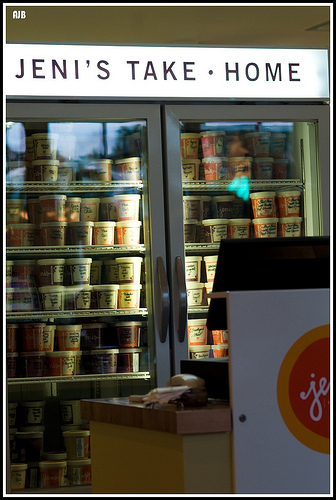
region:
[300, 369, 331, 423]
White writing on an orange background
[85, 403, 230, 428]
A brown counter top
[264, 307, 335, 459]
An orange circle surrounded by a yellow circle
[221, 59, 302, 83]
Black lettered word on white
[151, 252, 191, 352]
Handles on a refrigerated case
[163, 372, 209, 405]
Telephone on a counter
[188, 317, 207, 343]
Orange and white container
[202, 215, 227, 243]
Brown and white container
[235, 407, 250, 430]
Metal round circle on white background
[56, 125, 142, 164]
Reflections of the outside on glass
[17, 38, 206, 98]
Lighted sign on display.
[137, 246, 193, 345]
Metal handles on doors.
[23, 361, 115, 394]
Wire shelving in unit.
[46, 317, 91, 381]
Containers of ice cream.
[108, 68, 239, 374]
Refridgerated unit holding containers.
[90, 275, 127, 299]
White lid on container.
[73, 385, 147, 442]
Wood counter top on base.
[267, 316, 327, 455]
Red and orange logo on counter.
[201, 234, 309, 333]
Black monitor in store.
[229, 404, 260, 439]
Screw holding sign to counter.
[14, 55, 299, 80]
Black letters on white sign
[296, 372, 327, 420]
White letters on sign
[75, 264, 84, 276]
Black lettering on container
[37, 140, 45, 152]
Black lettering on container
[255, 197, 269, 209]
Black lettering on orange container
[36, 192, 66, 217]
Orange container behind glass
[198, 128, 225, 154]
Container behind glass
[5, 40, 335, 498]
Clear glass doors below white sign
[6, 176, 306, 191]
White rack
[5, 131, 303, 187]
White rack under containers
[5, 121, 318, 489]
A display of ice cream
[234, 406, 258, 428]
A small black screw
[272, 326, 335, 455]
A logo on the counter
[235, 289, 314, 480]
A white cashier's stand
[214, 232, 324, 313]
A black electronic screen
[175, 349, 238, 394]
A black cash register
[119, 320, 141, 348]
Chocolate ice cream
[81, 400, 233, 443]
A wooden counter top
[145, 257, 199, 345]
Silver door handles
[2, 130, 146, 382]
A glass case containing the ice cream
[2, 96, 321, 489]
this is a store refrigerator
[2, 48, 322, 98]
a white sign on the front of the refrigerator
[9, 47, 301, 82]
the letters are black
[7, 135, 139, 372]
many containers in the fridge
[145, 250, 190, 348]
the handles are silver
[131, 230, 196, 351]
the handles are made of metal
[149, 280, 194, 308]
a reflection of light on the handles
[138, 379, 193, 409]
papers on the counter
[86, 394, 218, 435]
the counter is brown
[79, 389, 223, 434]
the top of the counter is made of wood